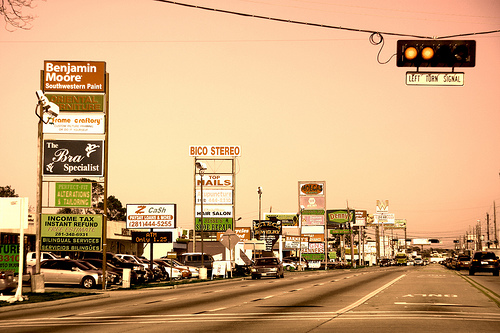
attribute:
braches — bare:
[4, 1, 41, 33]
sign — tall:
[39, 50, 117, 139]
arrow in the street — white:
[392, 290, 456, 314]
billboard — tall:
[26, 54, 117, 285]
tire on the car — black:
[74, 273, 97, 298]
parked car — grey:
[19, 249, 112, 298]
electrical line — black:
[226, 6, 335, 53]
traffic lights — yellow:
[402, 42, 439, 69]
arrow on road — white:
[372, 286, 472, 318]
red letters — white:
[184, 139, 247, 165]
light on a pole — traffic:
[393, 43, 437, 71]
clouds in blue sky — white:
[107, 38, 213, 119]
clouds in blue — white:
[391, 112, 460, 210]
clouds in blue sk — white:
[293, 6, 381, 81]